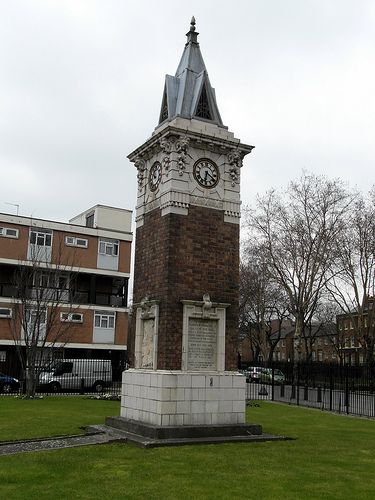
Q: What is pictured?
A: A clock tower.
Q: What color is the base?
A: White.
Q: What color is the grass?
A: Green.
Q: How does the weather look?
A: Overcast.